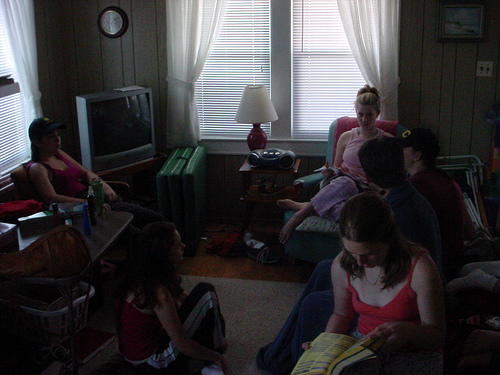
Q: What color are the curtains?
A: White.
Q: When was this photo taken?
A: During the day.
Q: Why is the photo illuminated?
A: Windows.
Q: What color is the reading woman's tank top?
A: Red.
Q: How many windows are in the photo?
A: 2.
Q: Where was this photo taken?
A: In the family room.